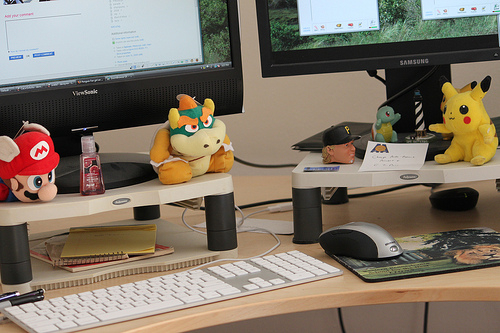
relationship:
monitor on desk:
[252, 0, 500, 82] [1, 143, 500, 332]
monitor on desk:
[1, 1, 248, 130] [1, 143, 500, 332]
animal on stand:
[425, 75, 500, 167] [287, 123, 500, 247]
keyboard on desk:
[2, 247, 347, 332] [1, 143, 500, 332]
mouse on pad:
[317, 217, 404, 263] [320, 225, 500, 284]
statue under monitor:
[405, 88, 434, 140] [252, 0, 500, 82]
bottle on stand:
[75, 134, 107, 198] [1, 144, 242, 295]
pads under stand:
[29, 224, 178, 275] [1, 144, 242, 295]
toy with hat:
[2, 120, 62, 208] [1, 128, 62, 182]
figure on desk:
[149, 94, 236, 189] [1, 143, 500, 332]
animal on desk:
[425, 75, 500, 167] [1, 143, 500, 332]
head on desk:
[323, 124, 360, 165] [1, 143, 500, 332]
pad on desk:
[320, 225, 500, 284] [1, 143, 500, 332]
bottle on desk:
[75, 134, 107, 198] [1, 143, 500, 332]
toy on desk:
[2, 120, 62, 208] [1, 143, 500, 332]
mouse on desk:
[317, 217, 404, 263] [1, 143, 500, 332]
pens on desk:
[1, 284, 45, 310] [1, 143, 500, 332]